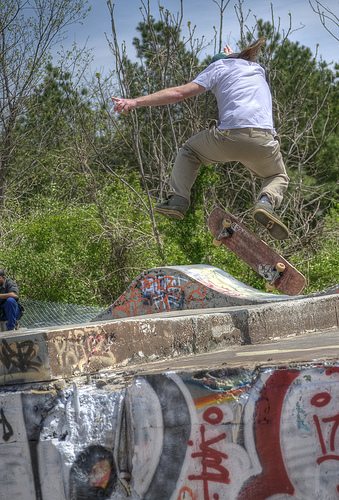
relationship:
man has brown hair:
[110, 35, 291, 240] [220, 30, 294, 73]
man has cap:
[110, 35, 291, 240] [209, 50, 227, 66]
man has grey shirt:
[110, 35, 291, 240] [209, 62, 264, 112]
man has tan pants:
[110, 35, 291, 240] [188, 128, 257, 164]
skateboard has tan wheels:
[206, 204, 309, 300] [270, 259, 293, 276]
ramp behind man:
[91, 262, 295, 320] [110, 35, 291, 240]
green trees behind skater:
[31, 117, 183, 310] [100, 37, 304, 242]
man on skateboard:
[108, 31, 297, 243] [198, 202, 318, 308]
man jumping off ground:
[108, 31, 297, 243] [1, 292, 325, 394]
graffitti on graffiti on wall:
[118, 395, 277, 498] [0, 365, 339, 499]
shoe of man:
[145, 183, 201, 230] [108, 31, 297, 243]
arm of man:
[77, 62, 217, 122] [108, 31, 297, 243]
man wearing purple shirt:
[108, 31, 297, 243] [184, 59, 288, 134]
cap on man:
[206, 43, 228, 65] [108, 47, 291, 241]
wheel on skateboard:
[222, 218, 235, 228] [206, 204, 309, 300]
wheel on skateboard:
[214, 234, 224, 245] [206, 204, 309, 300]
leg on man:
[157, 124, 235, 215] [124, 43, 294, 252]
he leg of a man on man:
[246, 150, 289, 201] [124, 43, 294, 252]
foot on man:
[153, 196, 196, 223] [124, 43, 294, 252]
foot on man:
[239, 178, 302, 241] [108, 31, 297, 243]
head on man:
[201, 51, 240, 72] [108, 47, 291, 241]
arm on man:
[142, 58, 222, 111] [117, 48, 300, 235]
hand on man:
[103, 92, 139, 114] [120, 34, 303, 253]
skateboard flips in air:
[187, 203, 315, 306] [125, 176, 322, 310]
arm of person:
[142, 58, 222, 111] [110, 36, 315, 249]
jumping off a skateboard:
[110, 34, 291, 241] [206, 204, 309, 300]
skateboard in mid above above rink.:
[202, 189, 319, 317] [0, 210, 339, 498]